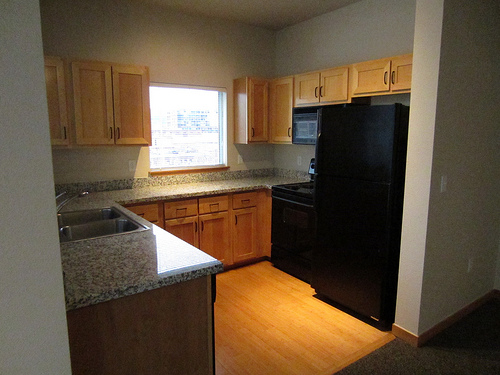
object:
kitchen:
[36, 1, 416, 375]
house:
[0, 0, 500, 375]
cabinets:
[125, 190, 262, 266]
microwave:
[292, 109, 318, 146]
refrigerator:
[310, 103, 410, 328]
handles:
[177, 203, 221, 233]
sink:
[51, 205, 149, 245]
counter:
[53, 205, 157, 302]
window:
[148, 85, 227, 169]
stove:
[283, 182, 315, 193]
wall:
[394, 0, 500, 336]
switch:
[441, 176, 447, 192]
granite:
[136, 195, 169, 204]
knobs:
[382, 70, 389, 86]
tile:
[215, 278, 292, 363]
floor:
[214, 259, 499, 375]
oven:
[292, 109, 318, 146]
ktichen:
[50, 147, 394, 375]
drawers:
[165, 192, 259, 220]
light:
[161, 91, 206, 101]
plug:
[468, 258, 479, 272]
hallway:
[352, 298, 500, 366]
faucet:
[56, 191, 90, 214]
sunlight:
[154, 168, 187, 171]